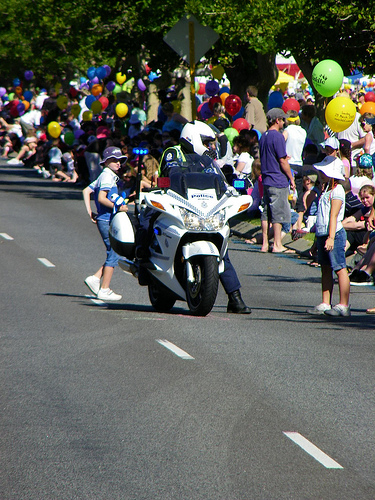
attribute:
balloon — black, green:
[311, 58, 343, 96]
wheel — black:
[177, 238, 220, 318]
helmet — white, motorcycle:
[180, 120, 216, 157]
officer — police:
[154, 118, 250, 313]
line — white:
[283, 429, 343, 470]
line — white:
[155, 337, 195, 359]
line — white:
[85, 294, 104, 303]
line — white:
[36, 256, 55, 266]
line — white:
[0, 232, 13, 240]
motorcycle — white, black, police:
[119, 136, 264, 309]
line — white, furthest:
[127, 319, 255, 403]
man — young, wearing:
[258, 105, 299, 256]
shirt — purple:
[256, 129, 288, 185]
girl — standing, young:
[299, 152, 358, 328]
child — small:
[312, 136, 358, 327]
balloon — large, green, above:
[311, 58, 345, 99]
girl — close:
[312, 158, 350, 317]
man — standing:
[259, 106, 295, 252]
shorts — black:
[260, 182, 291, 223]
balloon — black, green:
[297, 53, 356, 103]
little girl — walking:
[83, 145, 128, 304]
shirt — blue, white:
[89, 167, 121, 191]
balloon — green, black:
[310, 54, 345, 100]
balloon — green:
[312, 54, 346, 96]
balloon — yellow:
[324, 95, 357, 132]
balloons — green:
[310, 55, 356, 137]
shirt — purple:
[242, 128, 307, 187]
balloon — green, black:
[298, 53, 344, 101]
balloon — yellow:
[308, 82, 361, 148]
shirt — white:
[308, 185, 360, 249]